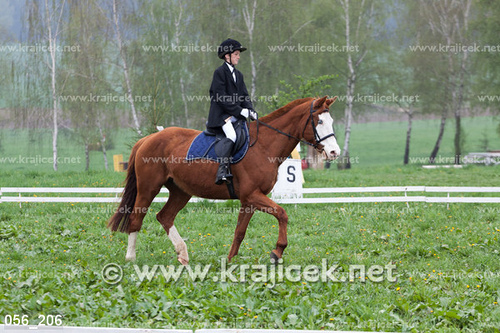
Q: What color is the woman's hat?
A: Black.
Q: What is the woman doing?
A: Riding.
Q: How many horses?
A: One.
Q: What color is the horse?
A: Brown.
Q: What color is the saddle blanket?
A: Blue.